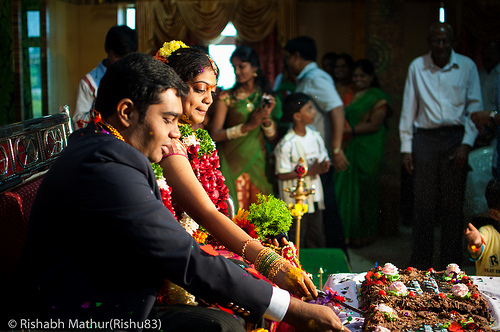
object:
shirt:
[397, 47, 485, 155]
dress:
[215, 84, 283, 216]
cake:
[354, 262, 500, 332]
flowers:
[444, 262, 463, 278]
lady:
[149, 37, 319, 332]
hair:
[166, 47, 221, 83]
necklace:
[98, 118, 128, 143]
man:
[1, 51, 352, 332]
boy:
[461, 175, 499, 277]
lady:
[331, 57, 396, 247]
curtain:
[135, 1, 300, 81]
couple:
[8, 40, 353, 332]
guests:
[279, 34, 353, 277]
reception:
[1, 0, 497, 332]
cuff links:
[226, 302, 234, 308]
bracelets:
[241, 238, 262, 260]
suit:
[1, 120, 274, 332]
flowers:
[195, 153, 216, 173]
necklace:
[239, 88, 261, 109]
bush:
[247, 191, 294, 242]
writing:
[411, 278, 442, 297]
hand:
[463, 221, 483, 248]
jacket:
[71, 57, 111, 133]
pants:
[409, 125, 472, 274]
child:
[272, 91, 332, 248]